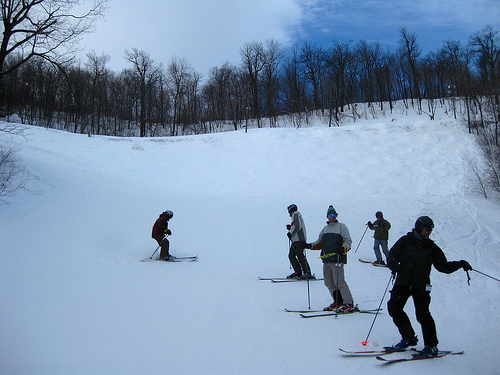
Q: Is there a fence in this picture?
A: No, there are no fences.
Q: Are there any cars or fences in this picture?
A: No, there are no fences or cars.